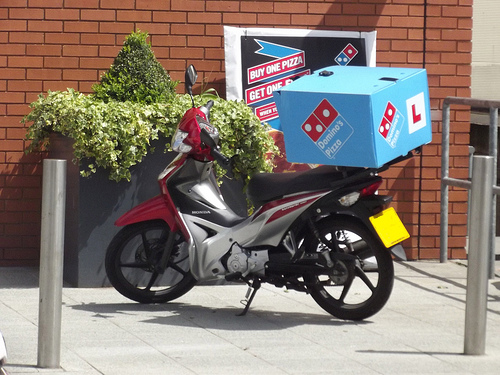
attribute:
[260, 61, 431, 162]
box — blue, red, white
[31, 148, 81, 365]
post — silver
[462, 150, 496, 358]
post — silver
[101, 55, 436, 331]
motorcycle — red, silver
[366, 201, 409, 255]
plate — yellow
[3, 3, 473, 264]
wall — red, brick